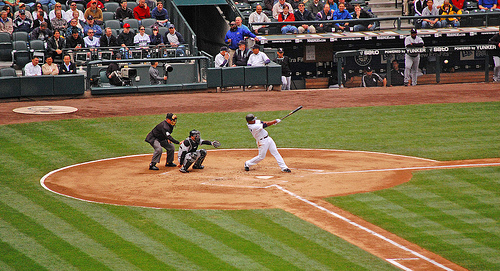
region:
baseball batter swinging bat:
[239, 104, 302, 174]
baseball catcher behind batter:
[176, 105, 303, 175]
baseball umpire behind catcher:
[145, 115, 222, 173]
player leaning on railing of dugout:
[332, 27, 498, 87]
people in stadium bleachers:
[0, 0, 496, 76]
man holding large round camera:
[146, 57, 174, 85]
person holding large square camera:
[102, 59, 140, 88]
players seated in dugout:
[281, 44, 498, 89]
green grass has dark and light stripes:
[0, 103, 498, 269]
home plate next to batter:
[242, 106, 302, 182]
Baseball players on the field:
[128, 92, 355, 188]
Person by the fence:
[390, 21, 437, 93]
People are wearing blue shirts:
[212, 8, 261, 47]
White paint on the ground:
[251, 169, 468, 269]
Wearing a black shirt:
[138, 110, 179, 157]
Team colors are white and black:
[230, 100, 302, 180]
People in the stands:
[1, 3, 498, 95]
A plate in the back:
[11, 101, 84, 126]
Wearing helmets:
[156, 108, 218, 150]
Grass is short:
[31, 208, 233, 253]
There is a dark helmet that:
[241, 103, 256, 141]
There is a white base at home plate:
[256, 170, 271, 182]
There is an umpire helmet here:
[166, 113, 188, 147]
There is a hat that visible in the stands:
[251, 38, 264, 54]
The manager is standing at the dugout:
[408, 26, 425, 83]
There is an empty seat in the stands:
[16, 35, 26, 52]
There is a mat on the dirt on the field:
[13, 92, 99, 157]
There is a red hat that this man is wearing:
[122, 16, 131, 36]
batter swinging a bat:
[243, 100, 306, 172]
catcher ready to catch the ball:
[171, 123, 226, 173]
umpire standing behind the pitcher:
[142, 108, 182, 173]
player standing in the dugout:
[402, 28, 424, 87]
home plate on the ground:
[253, 169, 278, 188]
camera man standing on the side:
[143, 54, 174, 89]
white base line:
[281, 159, 493, 179]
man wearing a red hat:
[118, 21, 139, 43]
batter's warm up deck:
[10, 95, 85, 122]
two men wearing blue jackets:
[223, 15, 256, 47]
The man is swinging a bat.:
[241, 103, 303, 177]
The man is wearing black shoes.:
[243, 107, 305, 177]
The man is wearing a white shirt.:
[241, 107, 306, 176]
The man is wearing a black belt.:
[239, 108, 303, 175]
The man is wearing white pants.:
[244, 103, 305, 171]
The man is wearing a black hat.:
[243, 107, 305, 175]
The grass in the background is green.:
[392, 112, 477, 149]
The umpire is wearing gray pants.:
[144, 111, 178, 168]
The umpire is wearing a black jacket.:
[145, 107, 182, 169]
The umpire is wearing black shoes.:
[145, 101, 178, 171]